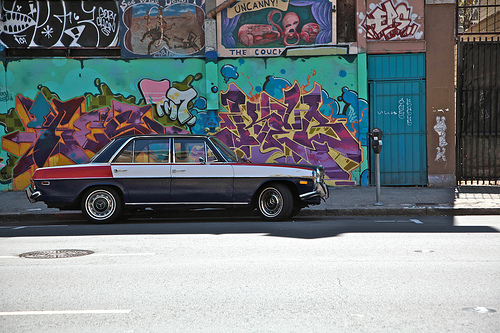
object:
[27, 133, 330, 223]
car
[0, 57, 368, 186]
graffiti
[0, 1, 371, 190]
wall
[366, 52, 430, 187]
door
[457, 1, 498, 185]
gate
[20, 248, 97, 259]
cover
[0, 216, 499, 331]
road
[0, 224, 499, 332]
street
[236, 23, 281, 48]
couch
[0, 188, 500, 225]
sidewalk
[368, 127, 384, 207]
meter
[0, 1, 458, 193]
building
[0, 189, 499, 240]
shadow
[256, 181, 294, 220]
wheel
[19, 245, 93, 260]
whole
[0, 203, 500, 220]
curb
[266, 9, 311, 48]
octopus